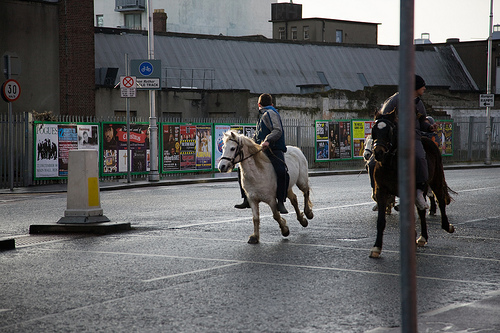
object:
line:
[143, 262, 245, 284]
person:
[233, 93, 290, 213]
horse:
[218, 129, 316, 244]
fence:
[0, 112, 499, 192]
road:
[0, 167, 500, 333]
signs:
[161, 122, 180, 170]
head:
[370, 110, 395, 162]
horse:
[370, 112, 453, 258]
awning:
[95, 32, 479, 95]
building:
[95, 26, 480, 177]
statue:
[55, 149, 111, 226]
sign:
[121, 76, 137, 97]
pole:
[398, 0, 418, 333]